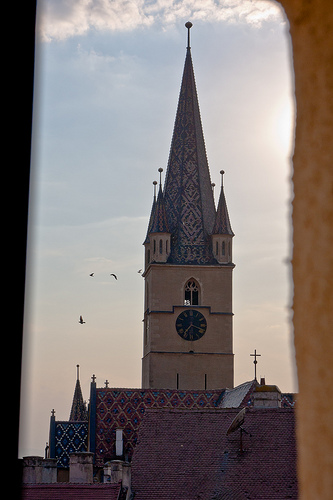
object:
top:
[140, 19, 236, 272]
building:
[18, 21, 294, 499]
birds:
[78, 268, 146, 327]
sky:
[17, 4, 295, 456]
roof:
[92, 379, 276, 455]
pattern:
[94, 387, 219, 464]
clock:
[174, 305, 210, 345]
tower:
[141, 20, 234, 390]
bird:
[76, 316, 86, 324]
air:
[31, 224, 145, 341]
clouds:
[36, 2, 273, 57]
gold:
[177, 310, 203, 321]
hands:
[183, 324, 201, 347]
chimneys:
[25, 448, 130, 499]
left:
[0, 8, 81, 479]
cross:
[248, 346, 261, 389]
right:
[305, 37, 328, 498]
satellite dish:
[223, 407, 256, 465]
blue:
[48, 410, 87, 475]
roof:
[47, 420, 110, 481]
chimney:
[62, 451, 97, 493]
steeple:
[160, 13, 215, 257]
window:
[182, 278, 204, 309]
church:
[15, 22, 293, 499]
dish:
[224, 405, 251, 437]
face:
[179, 313, 202, 338]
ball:
[182, 21, 196, 31]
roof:
[130, 409, 292, 498]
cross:
[48, 404, 55, 420]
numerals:
[173, 314, 188, 334]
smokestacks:
[29, 460, 127, 476]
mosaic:
[95, 390, 221, 456]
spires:
[129, 48, 253, 265]